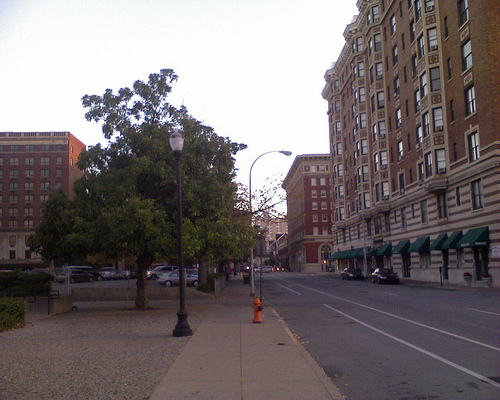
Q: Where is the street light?
A: On the side walk.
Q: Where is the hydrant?
A: On the sidewalk.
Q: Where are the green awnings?
A: On the right building.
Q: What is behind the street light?
A: Tree.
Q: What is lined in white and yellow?
A: Road.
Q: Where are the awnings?
A: On the building.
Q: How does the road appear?
A: Tamacked.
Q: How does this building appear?
A: Tall.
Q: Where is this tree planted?
A: Side of street.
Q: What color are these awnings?
A: Green.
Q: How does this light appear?
A: Curved at top.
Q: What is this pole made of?
A: Metal.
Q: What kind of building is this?
A: Highrise.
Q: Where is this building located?
A: On the left.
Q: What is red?
A: The building.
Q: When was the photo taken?
A: Day time.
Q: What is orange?
A: The fire hydrant.